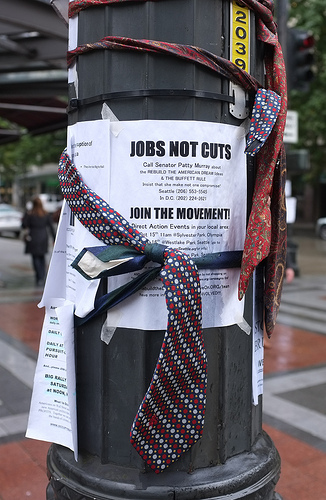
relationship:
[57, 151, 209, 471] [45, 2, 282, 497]
tie around pole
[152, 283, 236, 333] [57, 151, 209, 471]
dots on tie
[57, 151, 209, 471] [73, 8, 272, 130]
tie on pole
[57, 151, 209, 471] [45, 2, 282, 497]
tie on pole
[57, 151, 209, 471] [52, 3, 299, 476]
tie tied around pole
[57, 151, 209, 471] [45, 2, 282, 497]
tie tied around pole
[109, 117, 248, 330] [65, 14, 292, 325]
paper on pole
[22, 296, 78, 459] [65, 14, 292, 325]
paper on pole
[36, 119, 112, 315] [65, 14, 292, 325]
paper on pole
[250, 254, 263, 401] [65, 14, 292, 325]
paper on pole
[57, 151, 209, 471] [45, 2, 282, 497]
tie tied on pole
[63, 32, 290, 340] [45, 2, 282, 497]
tie tied on pole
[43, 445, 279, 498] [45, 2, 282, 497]
base on pole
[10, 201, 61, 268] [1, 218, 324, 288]
woman on road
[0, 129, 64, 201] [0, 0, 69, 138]
plants near building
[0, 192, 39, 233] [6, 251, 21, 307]
car parked near road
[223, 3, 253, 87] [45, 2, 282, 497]
numbers on pole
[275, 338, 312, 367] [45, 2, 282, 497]
floor tiles near pole